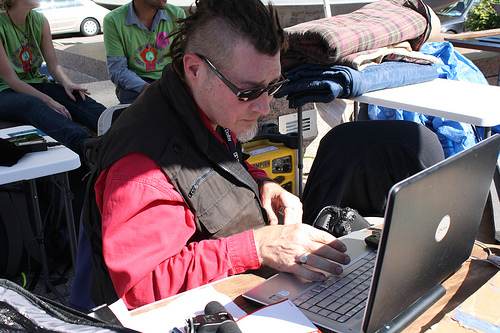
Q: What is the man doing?
A: Looking at laptop.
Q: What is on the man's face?
A: Sunglasses.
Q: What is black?
A: Man's vest.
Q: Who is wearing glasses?
A: The man.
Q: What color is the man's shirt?
A: Red.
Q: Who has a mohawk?
A: The man.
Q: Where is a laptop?
A: On the table.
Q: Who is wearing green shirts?
A: Two people in background.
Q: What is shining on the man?
A: Sunshine.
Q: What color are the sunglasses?
A: Black.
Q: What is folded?
A: Blankets.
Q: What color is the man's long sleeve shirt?
A: Red.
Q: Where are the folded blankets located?
A: On a table.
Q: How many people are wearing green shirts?
A: 2.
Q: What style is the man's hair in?
A: Mohawk.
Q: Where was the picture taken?
A: Outside at table.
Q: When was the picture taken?
A: Daytime.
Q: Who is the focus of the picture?
A: A man.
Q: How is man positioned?
A: Sitting.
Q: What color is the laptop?
A: Black.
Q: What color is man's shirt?
A: Red.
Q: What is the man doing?
A: Working on laptop.